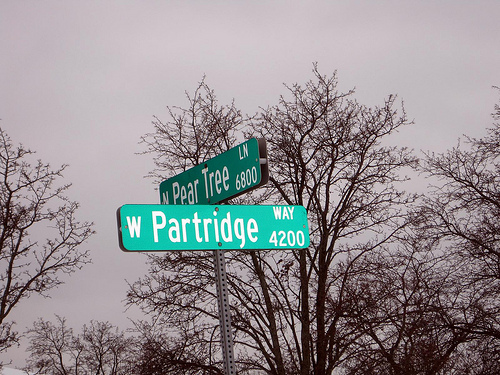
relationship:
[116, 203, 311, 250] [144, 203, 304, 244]
sign with writing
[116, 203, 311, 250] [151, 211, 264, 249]
sign with writing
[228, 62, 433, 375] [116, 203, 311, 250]
bare trees behind sign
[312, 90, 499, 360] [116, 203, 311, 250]
bare trees to right of sign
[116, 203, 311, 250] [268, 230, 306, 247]
sign with numbers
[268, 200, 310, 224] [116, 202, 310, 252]
word on background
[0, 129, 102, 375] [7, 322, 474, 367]
tree in field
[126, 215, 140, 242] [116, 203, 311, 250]
letter on sign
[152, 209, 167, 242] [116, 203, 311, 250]
letter on sign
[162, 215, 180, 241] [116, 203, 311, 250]
letter on sign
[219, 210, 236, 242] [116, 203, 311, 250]
letter on sign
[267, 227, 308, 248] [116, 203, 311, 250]
numbers on sign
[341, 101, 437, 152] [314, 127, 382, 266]
leaves on branches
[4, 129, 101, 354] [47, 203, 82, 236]
tree has branches